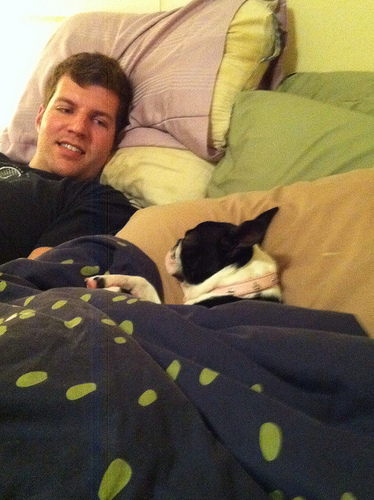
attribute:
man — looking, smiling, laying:
[4, 51, 136, 244]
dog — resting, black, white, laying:
[134, 202, 291, 307]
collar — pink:
[186, 277, 282, 297]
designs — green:
[17, 303, 142, 418]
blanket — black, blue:
[13, 308, 361, 479]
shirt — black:
[1, 163, 127, 245]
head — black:
[163, 219, 275, 292]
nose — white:
[164, 234, 185, 275]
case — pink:
[84, 10, 268, 126]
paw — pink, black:
[85, 261, 166, 310]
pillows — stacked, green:
[232, 69, 372, 182]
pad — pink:
[86, 278, 96, 288]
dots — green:
[8, 295, 115, 397]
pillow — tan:
[145, 187, 366, 316]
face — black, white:
[169, 219, 211, 280]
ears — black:
[224, 193, 285, 256]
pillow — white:
[105, 11, 282, 175]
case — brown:
[273, 180, 368, 310]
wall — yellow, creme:
[280, 0, 373, 79]